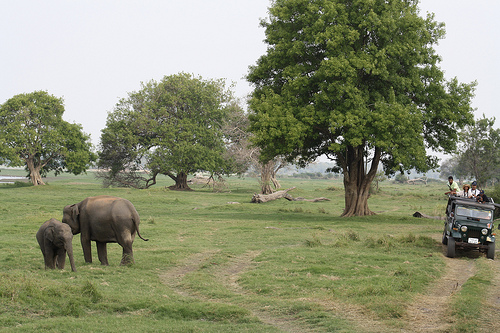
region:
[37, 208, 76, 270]
The elephant on the left.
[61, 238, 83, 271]
The trunk of the elephant on the left.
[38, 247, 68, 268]
The front legs of the elephant on the left.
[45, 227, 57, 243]
The ear of the elephant on the left.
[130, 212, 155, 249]
The tail of the elephant on the right.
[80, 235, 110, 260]
The front legs of the elephant on the right.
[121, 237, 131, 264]
The back legs of the elephant on the right.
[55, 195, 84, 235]
The head of the elephant on the right.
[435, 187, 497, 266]
The jeep the people are riding in.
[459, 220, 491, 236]
The front headlights of the jeep.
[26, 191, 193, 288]
two elephants on the grass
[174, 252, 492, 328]
vehicle tracks in the grass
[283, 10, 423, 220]
the largest green tree with leaves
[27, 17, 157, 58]
the sky is clear and bright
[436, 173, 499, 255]
the people in the vehicle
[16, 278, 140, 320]
the patch of grass beside the elephants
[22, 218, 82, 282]
the infant elephant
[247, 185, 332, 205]
the tree trunk on the grass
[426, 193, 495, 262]
the vehicle is dark green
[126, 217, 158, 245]
the tail of the elephant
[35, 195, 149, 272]
two elephants standing together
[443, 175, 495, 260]
people riding in truck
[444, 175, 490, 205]
people leaning on top of truck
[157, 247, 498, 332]
rut marks in ground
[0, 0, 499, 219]
trees behind elephants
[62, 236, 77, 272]
elephant has long trunk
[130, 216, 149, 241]
elephant has curved tail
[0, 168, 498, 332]
truck driving on grass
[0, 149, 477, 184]
hill behind trees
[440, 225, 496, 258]
truck has black wheels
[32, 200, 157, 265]
elephants on a field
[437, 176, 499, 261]
jeep with people inside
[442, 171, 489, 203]
people hanging out of the jeep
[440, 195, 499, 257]
black jeep driving off road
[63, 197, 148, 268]
profile view of an elephant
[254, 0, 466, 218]
large tree in the background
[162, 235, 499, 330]
dirt path on the ground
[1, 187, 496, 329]
large grassy field with trees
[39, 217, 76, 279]
baby elephant standing in the grass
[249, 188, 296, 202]
large tree trunk laying on its side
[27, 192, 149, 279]
Elephants in a field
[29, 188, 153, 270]
Two elephants in a field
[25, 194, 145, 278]
A bit elephant and a small elephant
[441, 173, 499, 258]
Men in a truck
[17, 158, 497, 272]
Men watching elephants from a truck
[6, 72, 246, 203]
Large trees in the distance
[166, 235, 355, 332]
Two rutt road in the grass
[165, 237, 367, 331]
Tire tracks in the grass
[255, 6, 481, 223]
One large tree near a truck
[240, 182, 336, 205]
A dead tree on the ground